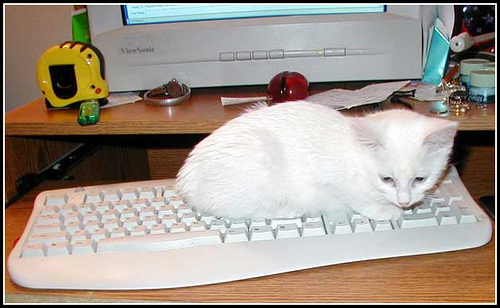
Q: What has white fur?
A: The cat.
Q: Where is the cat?
A: On the keyboard.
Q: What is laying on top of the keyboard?
A: Kitten.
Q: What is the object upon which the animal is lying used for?
A: Typing.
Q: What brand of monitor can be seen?
A: ViewSonic.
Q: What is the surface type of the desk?
A: Wood Grain.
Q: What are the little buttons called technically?
A: Keys.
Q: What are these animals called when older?
A: Cat.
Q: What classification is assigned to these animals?
A: Felines.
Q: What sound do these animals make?
A: Meow.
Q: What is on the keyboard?
A: A kitten.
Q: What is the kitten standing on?
A: A keyboard.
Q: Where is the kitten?
A: On a keyboard.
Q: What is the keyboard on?
A: A desk.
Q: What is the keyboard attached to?
A: A computer.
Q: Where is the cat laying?
A: Keyboard.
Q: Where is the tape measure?
A: On the desk.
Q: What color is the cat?
A: White.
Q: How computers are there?
A: One.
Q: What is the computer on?
A: Desk.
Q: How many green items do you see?
A: Two.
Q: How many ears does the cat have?
A: Two.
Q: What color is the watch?
A: Silver.